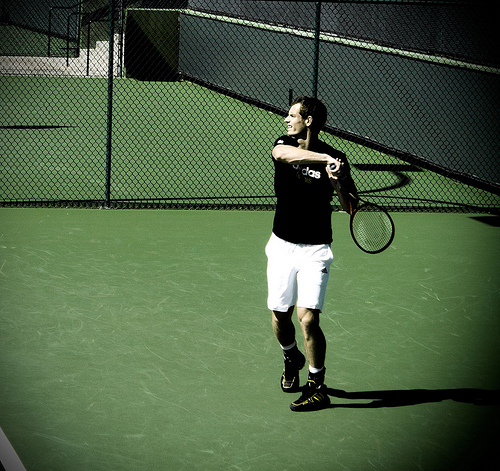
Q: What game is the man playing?
A: Tennis.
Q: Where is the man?
A: On a tennis court.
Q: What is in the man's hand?
A: Tennis racket.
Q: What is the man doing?
A: Playing tennis.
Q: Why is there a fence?
A: To divide the tennis courts.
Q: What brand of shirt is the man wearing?
A: Adidas.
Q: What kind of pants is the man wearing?
A: White shorts.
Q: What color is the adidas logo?
A: White.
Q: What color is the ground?
A: Green.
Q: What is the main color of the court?
A: Green.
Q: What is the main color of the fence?
A: Black.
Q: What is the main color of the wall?
A: Blue.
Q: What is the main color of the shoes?
A: Black.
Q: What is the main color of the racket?
A: Black.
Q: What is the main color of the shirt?
A: Black.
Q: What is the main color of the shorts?
A: White.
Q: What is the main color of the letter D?
A: White.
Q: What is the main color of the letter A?
A: White.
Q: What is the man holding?
A: A tennis racket.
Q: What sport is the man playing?
A: Tennis.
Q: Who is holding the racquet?
A: The man.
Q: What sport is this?
A: Tennis.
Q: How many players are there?
A: 1.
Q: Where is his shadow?
A: On the ground.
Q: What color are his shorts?
A: White.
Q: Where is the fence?
A: Behind the player.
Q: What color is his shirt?
A: Black.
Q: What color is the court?
A: Green.